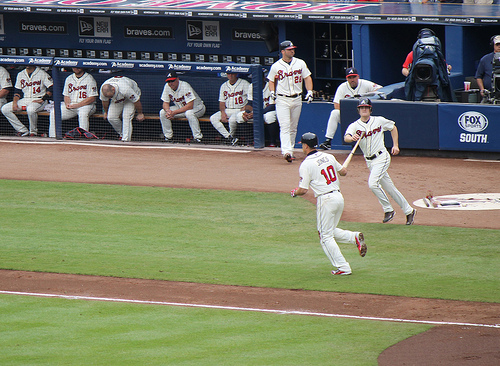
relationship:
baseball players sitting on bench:
[0, 52, 268, 139] [14, 106, 254, 145]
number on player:
[319, 163, 337, 186] [283, 127, 376, 277]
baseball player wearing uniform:
[338, 100, 415, 222] [345, 115, 414, 211]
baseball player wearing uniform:
[280, 132, 370, 277] [298, 152, 355, 272]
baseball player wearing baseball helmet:
[291, 132, 367, 275] [298, 132, 319, 148]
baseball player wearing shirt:
[291, 132, 367, 275] [297, 148, 345, 197]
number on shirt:
[321, 165, 336, 185] [299, 151, 345, 196]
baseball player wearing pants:
[291, 132, 367, 275] [313, 183, 399, 283]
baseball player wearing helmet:
[291, 132, 367, 275] [296, 130, 318, 147]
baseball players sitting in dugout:
[242, 72, 276, 147] [2, 11, 279, 153]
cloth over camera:
[403, 30, 451, 101] [395, 33, 457, 105]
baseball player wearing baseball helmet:
[291, 132, 367, 275] [292, 130, 322, 152]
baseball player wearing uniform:
[291, 132, 367, 275] [295, 147, 359, 277]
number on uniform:
[319, 163, 337, 186] [295, 147, 359, 277]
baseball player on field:
[291, 132, 367, 275] [0, 134, 499, 364]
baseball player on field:
[344, 98, 417, 225] [0, 134, 499, 364]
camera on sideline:
[402, 37, 454, 102] [283, 17, 499, 153]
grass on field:
[0, 293, 435, 364] [0, 134, 499, 364]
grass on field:
[2, 178, 499, 303] [0, 134, 499, 364]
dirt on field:
[0, 139, 499, 227] [0, 134, 499, 364]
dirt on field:
[2, 268, 499, 364] [0, 134, 499, 364]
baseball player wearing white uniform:
[291, 132, 367, 275] [296, 152, 358, 271]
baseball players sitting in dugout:
[1, 63, 260, 138] [2, 11, 279, 153]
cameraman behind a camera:
[398, 27, 461, 122] [399, 30, 454, 104]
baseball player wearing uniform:
[344, 98, 417, 225] [341, 110, 413, 215]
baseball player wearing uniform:
[291, 132, 367, 275] [296, 148, 356, 268]